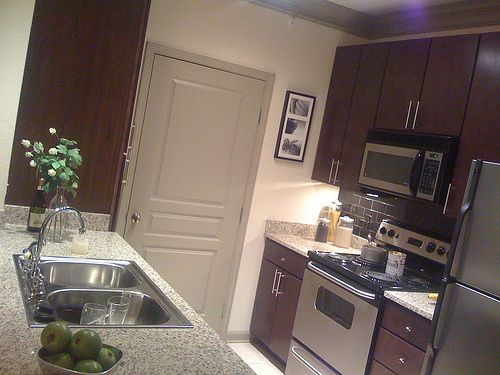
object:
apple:
[40, 320, 72, 354]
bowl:
[34, 338, 126, 374]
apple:
[70, 329, 105, 356]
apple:
[96, 347, 119, 369]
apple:
[73, 359, 104, 373]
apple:
[45, 353, 74, 368]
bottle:
[25, 175, 50, 232]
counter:
[1, 224, 255, 374]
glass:
[78, 301, 108, 325]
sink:
[44, 286, 170, 327]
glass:
[107, 296, 131, 326]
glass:
[120, 288, 144, 324]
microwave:
[356, 126, 460, 205]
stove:
[286, 224, 455, 374]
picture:
[274, 88, 316, 164]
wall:
[149, 0, 248, 344]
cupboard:
[375, 35, 478, 134]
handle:
[404, 101, 411, 130]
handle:
[412, 99, 419, 130]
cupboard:
[312, 43, 388, 190]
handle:
[327, 159, 334, 183]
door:
[118, 39, 277, 340]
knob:
[129, 212, 144, 225]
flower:
[47, 126, 57, 134]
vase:
[43, 183, 72, 245]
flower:
[18, 136, 32, 149]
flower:
[46, 166, 56, 178]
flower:
[28, 159, 37, 167]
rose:
[47, 169, 58, 177]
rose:
[21, 139, 32, 147]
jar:
[335, 226, 350, 247]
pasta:
[329, 210, 342, 243]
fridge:
[420, 157, 500, 374]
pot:
[360, 233, 388, 265]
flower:
[46, 147, 60, 156]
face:
[285, 259, 380, 375]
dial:
[378, 226, 388, 236]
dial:
[386, 228, 396, 238]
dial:
[423, 239, 437, 254]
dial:
[435, 244, 443, 256]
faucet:
[33, 205, 88, 259]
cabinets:
[310, 35, 499, 211]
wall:
[0, 12, 250, 343]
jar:
[333, 214, 355, 249]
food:
[334, 225, 352, 248]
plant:
[20, 127, 86, 197]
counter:
[267, 224, 364, 251]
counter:
[384, 288, 434, 316]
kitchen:
[0, 1, 499, 372]